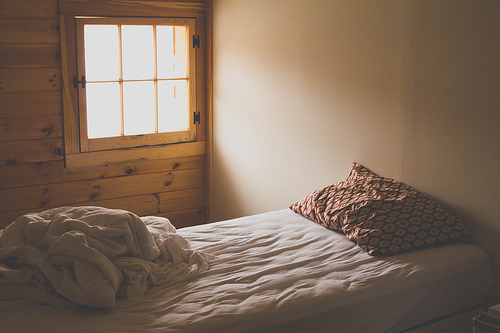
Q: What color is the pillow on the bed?
A: Red.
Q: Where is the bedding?
A: Crumpled.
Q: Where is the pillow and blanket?
A: On the bed.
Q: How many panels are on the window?
A: 6.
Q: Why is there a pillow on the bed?
A: For a head.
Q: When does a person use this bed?
A: At night.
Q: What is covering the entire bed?
A: A fitted sheet.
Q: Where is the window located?
A: On a wall.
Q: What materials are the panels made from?
A: Wood.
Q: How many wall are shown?
A: 2.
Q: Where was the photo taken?
A: In a bedroom.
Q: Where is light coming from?
A: A window.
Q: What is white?
A: Wall.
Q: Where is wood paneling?
A: On one wall.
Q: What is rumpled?
A: A blanket.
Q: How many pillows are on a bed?
A: One.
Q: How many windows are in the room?
A: One.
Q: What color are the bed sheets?
A: White.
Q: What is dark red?
A: Pillowcase.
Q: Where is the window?
A: On the wall.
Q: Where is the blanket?
A: On the bed.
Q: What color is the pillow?
A: Brown and black.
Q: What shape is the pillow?
A: Rectangular.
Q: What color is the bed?
A: White.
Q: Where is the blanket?
A: In a pile at the end of the bed.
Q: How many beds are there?
A: One.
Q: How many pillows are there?
A: One.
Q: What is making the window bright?
A: The sunlight.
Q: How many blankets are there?
A: One.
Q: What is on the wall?
A: Nothing.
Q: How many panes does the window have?
A: Six.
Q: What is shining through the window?
A: The sun.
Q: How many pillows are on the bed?
A: One.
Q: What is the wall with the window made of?
A: Wood.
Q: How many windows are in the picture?
A: One.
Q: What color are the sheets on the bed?
A: White.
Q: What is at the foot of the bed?
A: A blanket.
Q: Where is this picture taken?
A: A bedroom.